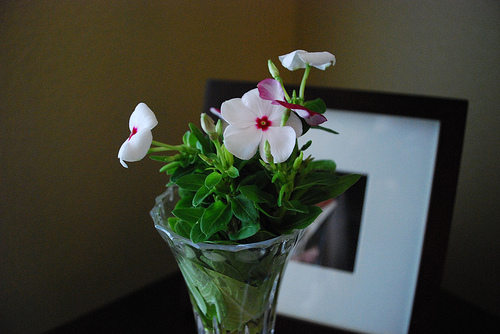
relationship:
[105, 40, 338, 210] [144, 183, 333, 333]
flower in vase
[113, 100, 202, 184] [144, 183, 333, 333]
flower in vase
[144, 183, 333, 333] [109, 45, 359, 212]
vase for flowers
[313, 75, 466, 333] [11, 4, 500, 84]
picture in background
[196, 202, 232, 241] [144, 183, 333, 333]
leaves in vase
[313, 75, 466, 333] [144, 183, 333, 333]
picture behind vase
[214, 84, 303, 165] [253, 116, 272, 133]
flower with pink stamen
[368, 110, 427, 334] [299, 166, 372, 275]
mat around picture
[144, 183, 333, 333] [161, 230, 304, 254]
vase with uneven edge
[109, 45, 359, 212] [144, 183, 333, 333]
flowers in a vase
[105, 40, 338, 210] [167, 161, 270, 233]
plant has leaves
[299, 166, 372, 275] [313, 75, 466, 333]
picture in a frame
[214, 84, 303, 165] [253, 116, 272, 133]
flower with red center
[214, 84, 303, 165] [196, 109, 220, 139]
flower has bud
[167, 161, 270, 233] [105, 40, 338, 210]
leaves of a plant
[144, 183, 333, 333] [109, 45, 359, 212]
vase with flowers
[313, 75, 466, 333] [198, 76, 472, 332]
picture in frame